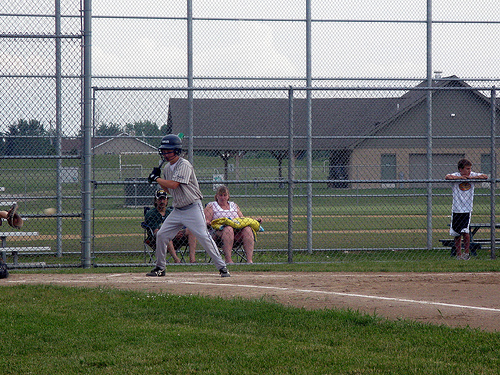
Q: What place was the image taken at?
A: It was taken at the field.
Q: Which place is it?
A: It is a field.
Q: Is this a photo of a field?
A: Yes, it is showing a field.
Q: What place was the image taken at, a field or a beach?
A: It was taken at a field.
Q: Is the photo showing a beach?
A: No, the picture is showing a field.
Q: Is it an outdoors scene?
A: Yes, it is outdoors.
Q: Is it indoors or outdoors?
A: It is outdoors.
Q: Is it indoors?
A: No, it is outdoors.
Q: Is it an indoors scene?
A: No, it is outdoors.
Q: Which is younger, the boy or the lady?
A: The boy is younger than the lady.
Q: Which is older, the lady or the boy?
A: The lady is older than the boy.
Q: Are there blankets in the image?
A: Yes, there is a blanket.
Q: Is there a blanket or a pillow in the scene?
A: Yes, there is a blanket.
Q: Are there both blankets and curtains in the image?
A: No, there is a blanket but no curtains.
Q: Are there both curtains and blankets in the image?
A: No, there is a blanket but no curtains.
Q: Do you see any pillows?
A: No, there are no pillows.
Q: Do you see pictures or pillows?
A: No, there are no pillows or pictures.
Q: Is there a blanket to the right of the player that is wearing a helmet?
A: Yes, there is a blanket to the right of the player.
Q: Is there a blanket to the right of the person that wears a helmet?
A: Yes, there is a blanket to the right of the player.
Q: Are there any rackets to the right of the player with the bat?
A: No, there is a blanket to the right of the player.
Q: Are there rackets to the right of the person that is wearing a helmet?
A: No, there is a blanket to the right of the player.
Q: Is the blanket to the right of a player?
A: Yes, the blanket is to the right of a player.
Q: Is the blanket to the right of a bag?
A: No, the blanket is to the right of a player.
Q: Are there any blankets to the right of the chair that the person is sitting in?
A: Yes, there is a blanket to the right of the chair.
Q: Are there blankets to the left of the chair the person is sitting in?
A: No, the blanket is to the right of the chair.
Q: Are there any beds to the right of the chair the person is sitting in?
A: No, there is a blanket to the right of the chair.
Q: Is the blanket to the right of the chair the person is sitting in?
A: Yes, the blanket is to the right of the chair.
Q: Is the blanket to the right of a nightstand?
A: No, the blanket is to the right of the chair.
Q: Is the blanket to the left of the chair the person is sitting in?
A: No, the blanket is to the right of the chair.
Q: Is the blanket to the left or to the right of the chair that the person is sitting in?
A: The blanket is to the right of the chair.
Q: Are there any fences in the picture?
A: Yes, there is a fence.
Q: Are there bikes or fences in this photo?
A: Yes, there is a fence.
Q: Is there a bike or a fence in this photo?
A: Yes, there is a fence.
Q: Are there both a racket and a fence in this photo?
A: No, there is a fence but no rackets.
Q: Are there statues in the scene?
A: No, there are no statues.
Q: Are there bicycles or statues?
A: No, there are no statues or bicycles.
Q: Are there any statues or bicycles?
A: No, there are no statues or bicycles.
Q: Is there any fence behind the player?
A: Yes, there is a fence behind the player.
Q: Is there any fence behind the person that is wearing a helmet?
A: Yes, there is a fence behind the player.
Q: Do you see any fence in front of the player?
A: No, the fence is behind the player.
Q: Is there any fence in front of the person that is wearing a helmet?
A: No, the fence is behind the player.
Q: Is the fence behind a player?
A: Yes, the fence is behind a player.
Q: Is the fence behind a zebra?
A: No, the fence is behind a player.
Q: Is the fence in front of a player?
A: No, the fence is behind a player.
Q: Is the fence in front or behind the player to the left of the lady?
A: The fence is behind the player.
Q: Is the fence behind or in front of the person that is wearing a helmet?
A: The fence is behind the player.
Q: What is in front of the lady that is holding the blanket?
A: The fence is in front of the lady.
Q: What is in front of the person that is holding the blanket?
A: The fence is in front of the lady.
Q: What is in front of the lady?
A: The fence is in front of the lady.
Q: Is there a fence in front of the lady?
A: Yes, there is a fence in front of the lady.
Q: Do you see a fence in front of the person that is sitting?
A: Yes, there is a fence in front of the lady.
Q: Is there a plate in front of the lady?
A: No, there is a fence in front of the lady.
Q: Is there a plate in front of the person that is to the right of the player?
A: No, there is a fence in front of the lady.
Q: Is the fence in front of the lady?
A: Yes, the fence is in front of the lady.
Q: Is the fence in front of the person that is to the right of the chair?
A: Yes, the fence is in front of the lady.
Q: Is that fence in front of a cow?
A: No, the fence is in front of the lady.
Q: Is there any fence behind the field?
A: Yes, there is a fence behind the field.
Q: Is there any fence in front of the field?
A: No, the fence is behind the field.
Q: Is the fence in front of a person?
A: Yes, the fence is in front of a person.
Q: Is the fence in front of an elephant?
A: No, the fence is in front of a person.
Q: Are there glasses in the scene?
A: No, there are no glasses.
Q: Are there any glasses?
A: No, there are no glasses.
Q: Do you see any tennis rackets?
A: No, there are no tennis rackets.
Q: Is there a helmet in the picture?
A: Yes, there is a helmet.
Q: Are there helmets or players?
A: Yes, there is a helmet.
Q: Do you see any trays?
A: No, there are no trays.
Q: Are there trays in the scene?
A: No, there are no trays.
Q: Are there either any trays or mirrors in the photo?
A: No, there are no trays or mirrors.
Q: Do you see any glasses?
A: No, there are no glasses.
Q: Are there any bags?
A: No, there are no bags.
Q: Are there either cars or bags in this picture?
A: No, there are no bags or cars.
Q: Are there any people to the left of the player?
A: Yes, there is a person to the left of the player.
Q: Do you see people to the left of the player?
A: Yes, there is a person to the left of the player.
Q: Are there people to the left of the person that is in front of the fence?
A: Yes, there is a person to the left of the player.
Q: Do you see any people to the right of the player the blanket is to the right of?
A: No, the person is to the left of the player.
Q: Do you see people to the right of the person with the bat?
A: No, the person is to the left of the player.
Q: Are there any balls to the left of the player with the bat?
A: No, there is a person to the left of the player.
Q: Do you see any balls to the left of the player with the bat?
A: No, there is a person to the left of the player.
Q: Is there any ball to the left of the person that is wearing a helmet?
A: No, there is a person to the left of the player.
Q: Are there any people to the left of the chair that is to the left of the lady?
A: Yes, there is a person to the left of the chair.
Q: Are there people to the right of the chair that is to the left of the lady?
A: No, the person is to the left of the chair.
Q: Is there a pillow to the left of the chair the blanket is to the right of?
A: No, there is a person to the left of the chair.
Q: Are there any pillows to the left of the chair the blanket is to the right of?
A: No, there is a person to the left of the chair.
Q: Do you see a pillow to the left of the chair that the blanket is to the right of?
A: No, there is a person to the left of the chair.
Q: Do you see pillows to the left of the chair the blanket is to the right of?
A: No, there is a person to the left of the chair.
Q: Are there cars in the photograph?
A: No, there are no cars.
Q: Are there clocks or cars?
A: No, there are no cars or clocks.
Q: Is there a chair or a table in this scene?
A: Yes, there is a chair.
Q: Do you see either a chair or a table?
A: Yes, there is a chair.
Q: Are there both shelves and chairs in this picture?
A: No, there is a chair but no shelves.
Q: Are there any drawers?
A: No, there are no drawers.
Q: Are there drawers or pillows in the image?
A: No, there are no drawers or pillows.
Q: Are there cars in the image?
A: No, there are no cars.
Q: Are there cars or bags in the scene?
A: No, there are no cars or bags.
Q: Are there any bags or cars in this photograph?
A: No, there are no cars or bags.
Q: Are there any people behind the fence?
A: Yes, there is a person behind the fence.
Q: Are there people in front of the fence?
A: No, the person is behind the fence.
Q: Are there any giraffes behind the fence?
A: No, there is a person behind the fence.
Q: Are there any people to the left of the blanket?
A: Yes, there is a person to the left of the blanket.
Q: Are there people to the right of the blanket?
A: No, the person is to the left of the blanket.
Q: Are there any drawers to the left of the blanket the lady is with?
A: No, there is a person to the left of the blanket.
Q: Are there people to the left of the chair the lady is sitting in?
A: Yes, there is a person to the left of the chair.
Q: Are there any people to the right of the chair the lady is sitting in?
A: No, the person is to the left of the chair.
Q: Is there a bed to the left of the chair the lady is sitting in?
A: No, there is a person to the left of the chair.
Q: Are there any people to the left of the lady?
A: Yes, there is a person to the left of the lady.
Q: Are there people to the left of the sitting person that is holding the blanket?
A: Yes, there is a person to the left of the lady.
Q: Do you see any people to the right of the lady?
A: No, the person is to the left of the lady.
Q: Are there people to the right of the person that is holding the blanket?
A: No, the person is to the left of the lady.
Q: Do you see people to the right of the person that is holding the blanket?
A: No, the person is to the left of the lady.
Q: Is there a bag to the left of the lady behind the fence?
A: No, there is a person to the left of the lady.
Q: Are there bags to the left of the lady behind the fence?
A: No, there is a person to the left of the lady.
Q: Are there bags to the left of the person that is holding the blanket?
A: No, there is a person to the left of the lady.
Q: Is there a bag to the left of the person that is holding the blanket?
A: No, there is a person to the left of the lady.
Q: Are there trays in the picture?
A: No, there are no trays.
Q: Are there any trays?
A: No, there are no trays.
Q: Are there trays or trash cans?
A: No, there are no trays or trash cans.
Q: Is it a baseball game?
A: Yes, this is a baseball game.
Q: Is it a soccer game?
A: No, this is a baseball game.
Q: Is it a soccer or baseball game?
A: This is a baseball game.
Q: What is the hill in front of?
A: The hill is in front of the building.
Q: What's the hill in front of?
A: The hill is in front of the building.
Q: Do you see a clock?
A: No, there are no clocks.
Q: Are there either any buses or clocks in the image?
A: No, there are no clocks or buses.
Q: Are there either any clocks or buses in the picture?
A: No, there are no clocks or buses.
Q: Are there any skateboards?
A: No, there are no skateboards.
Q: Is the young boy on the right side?
A: Yes, the boy is on the right of the image.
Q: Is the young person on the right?
A: Yes, the boy is on the right of the image.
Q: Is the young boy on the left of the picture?
A: No, the boy is on the right of the image.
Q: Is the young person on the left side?
A: No, the boy is on the right of the image.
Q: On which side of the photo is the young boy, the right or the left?
A: The boy is on the right of the image.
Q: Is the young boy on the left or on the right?
A: The boy is on the right of the image.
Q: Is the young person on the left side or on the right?
A: The boy is on the right of the image.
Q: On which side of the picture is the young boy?
A: The boy is on the right of the image.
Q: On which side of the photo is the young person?
A: The boy is on the right of the image.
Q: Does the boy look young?
A: Yes, the boy is young.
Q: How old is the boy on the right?
A: The boy is young.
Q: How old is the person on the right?
A: The boy is young.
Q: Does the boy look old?
A: No, the boy is young.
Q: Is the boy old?
A: No, the boy is young.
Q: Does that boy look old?
A: No, the boy is young.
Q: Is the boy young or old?
A: The boy is young.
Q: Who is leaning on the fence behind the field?
A: The boy is leaning on the fence.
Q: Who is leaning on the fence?
A: The boy is leaning on the fence.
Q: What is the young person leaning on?
A: The boy is leaning on the fence.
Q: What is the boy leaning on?
A: The boy is leaning on the fence.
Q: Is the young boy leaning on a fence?
A: Yes, the boy is leaning on a fence.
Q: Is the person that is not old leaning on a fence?
A: Yes, the boy is leaning on a fence.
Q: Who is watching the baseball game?
A: The boy is watching the game.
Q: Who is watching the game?
A: The boy is watching the game.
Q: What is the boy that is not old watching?
A: The boy is watching the game.